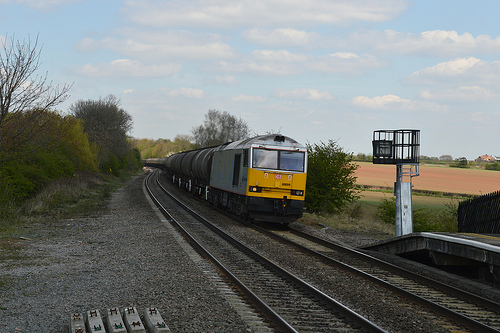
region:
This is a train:
[174, 141, 479, 273]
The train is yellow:
[207, 128, 377, 242]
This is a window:
[238, 149, 353, 166]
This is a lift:
[397, 118, 476, 187]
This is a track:
[165, 157, 255, 264]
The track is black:
[186, 236, 403, 308]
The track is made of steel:
[49, 110, 390, 327]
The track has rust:
[189, 203, 346, 311]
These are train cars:
[93, 158, 275, 227]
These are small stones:
[88, 213, 205, 292]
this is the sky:
[36, 18, 73, 53]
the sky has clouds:
[161, 7, 397, 77]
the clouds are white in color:
[191, 15, 275, 65]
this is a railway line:
[219, 230, 378, 326]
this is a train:
[158, 126, 310, 226]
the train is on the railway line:
[156, 135, 316, 225]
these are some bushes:
[6, 108, 127, 154]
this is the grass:
[71, 185, 109, 225]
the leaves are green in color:
[31, 129, 101, 161]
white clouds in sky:
[1, 1, 498, 135]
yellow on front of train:
[163, 134, 306, 219]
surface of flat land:
[352, 162, 497, 193]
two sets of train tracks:
[175, 221, 498, 331]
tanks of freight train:
[161, 145, 223, 182]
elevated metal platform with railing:
[372, 129, 420, 236]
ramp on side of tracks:
[365, 231, 497, 280]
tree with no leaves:
[0, 32, 71, 144]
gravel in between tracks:
[23, 227, 380, 332]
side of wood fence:
[455, 189, 499, 234]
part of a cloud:
[254, 55, 281, 80]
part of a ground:
[133, 254, 162, 281]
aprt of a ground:
[134, 218, 176, 270]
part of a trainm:
[275, 150, 297, 188]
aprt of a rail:
[212, 194, 233, 223]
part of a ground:
[167, 254, 199, 290]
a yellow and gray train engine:
[208, 131, 309, 220]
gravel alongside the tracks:
[111, 213, 178, 306]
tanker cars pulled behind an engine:
[163, 137, 223, 194]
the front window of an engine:
[253, 145, 278, 169]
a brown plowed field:
[348, 159, 498, 193]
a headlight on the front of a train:
[250, 184, 257, 190]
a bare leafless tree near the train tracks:
[0, 31, 79, 168]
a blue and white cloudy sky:
[2, 0, 498, 154]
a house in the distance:
[474, 151, 494, 163]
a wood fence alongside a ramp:
[456, 187, 499, 232]